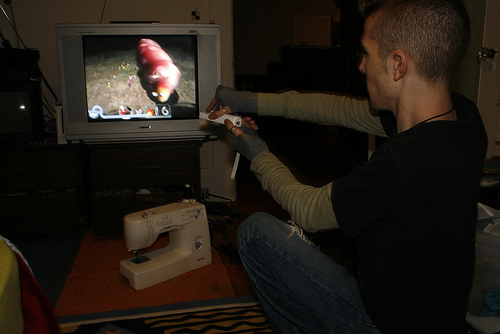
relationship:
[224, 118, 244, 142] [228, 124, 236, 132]
thumb has ring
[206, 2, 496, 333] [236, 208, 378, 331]
man wearing jeans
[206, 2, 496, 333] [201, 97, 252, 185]
man playing games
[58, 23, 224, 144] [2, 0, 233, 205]
television against wall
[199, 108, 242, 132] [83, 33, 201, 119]
control manipulates game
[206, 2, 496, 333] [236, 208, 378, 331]
gamer wearing jeans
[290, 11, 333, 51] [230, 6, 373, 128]
computer in background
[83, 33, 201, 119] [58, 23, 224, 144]
game on tv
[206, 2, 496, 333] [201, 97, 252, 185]
guy playing games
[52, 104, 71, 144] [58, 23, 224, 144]
console by tv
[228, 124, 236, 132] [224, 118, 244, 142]
ring on thumb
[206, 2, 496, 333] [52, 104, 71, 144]
man playing wii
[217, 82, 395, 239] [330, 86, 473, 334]
sleeves under shirt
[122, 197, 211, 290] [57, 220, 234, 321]
machine on blanket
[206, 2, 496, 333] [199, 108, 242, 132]
man holding mote